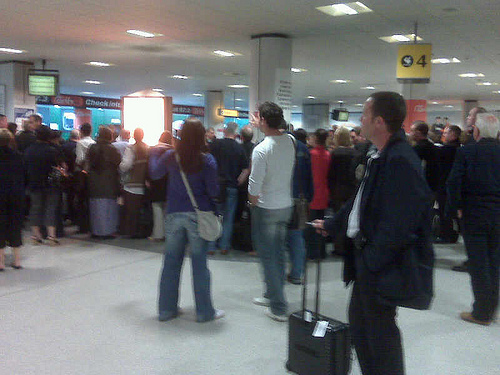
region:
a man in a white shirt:
[246, 101, 295, 322]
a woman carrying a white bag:
[143, 118, 228, 325]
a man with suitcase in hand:
[282, 88, 437, 374]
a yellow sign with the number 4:
[395, 36, 433, 82]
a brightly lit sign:
[120, 88, 173, 145]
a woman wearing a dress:
[80, 125, 127, 242]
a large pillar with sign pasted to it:
[249, 32, 293, 150]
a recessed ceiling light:
[313, 0, 374, 17]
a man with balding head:
[440, 111, 497, 326]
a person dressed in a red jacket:
[305, 126, 331, 261]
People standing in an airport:
[79, 128, 444, 265]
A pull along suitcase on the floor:
[287, 223, 350, 360]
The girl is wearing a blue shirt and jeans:
[153, 108, 230, 313]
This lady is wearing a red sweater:
[297, 118, 327, 223]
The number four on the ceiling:
[390, 36, 436, 77]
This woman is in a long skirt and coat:
[85, 138, 117, 238]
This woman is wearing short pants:
[0, 241, 26, 277]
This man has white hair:
[470, 108, 496, 144]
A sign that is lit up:
[217, 100, 239, 123]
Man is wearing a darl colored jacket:
[368, 132, 434, 303]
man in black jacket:
[357, 111, 438, 256]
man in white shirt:
[248, 108, 305, 255]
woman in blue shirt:
[162, 131, 238, 243]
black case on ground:
[290, 268, 345, 368]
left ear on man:
[369, 103, 389, 129]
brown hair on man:
[367, 99, 398, 129]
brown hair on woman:
[186, 130, 210, 174]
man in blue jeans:
[256, 194, 322, 311]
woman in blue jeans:
[164, 200, 242, 351]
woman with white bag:
[189, 157, 231, 259]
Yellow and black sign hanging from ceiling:
[392, 42, 436, 84]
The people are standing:
[0, 94, 492, 369]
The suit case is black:
[283, 217, 348, 367]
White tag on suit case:
[308, 319, 330, 339]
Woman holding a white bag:
[156, 119, 226, 324]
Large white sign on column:
[269, 62, 292, 120]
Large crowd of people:
[6, 102, 490, 374]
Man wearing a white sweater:
[248, 103, 308, 210]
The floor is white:
[3, 226, 495, 373]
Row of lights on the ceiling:
[38, 18, 491, 123]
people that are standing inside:
[58, 80, 475, 321]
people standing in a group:
[4, 51, 485, 374]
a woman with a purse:
[32, 80, 450, 291]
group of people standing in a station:
[55, 70, 476, 316]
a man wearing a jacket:
[314, 97, 440, 371]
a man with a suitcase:
[268, 137, 440, 372]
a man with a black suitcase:
[286, 141, 399, 366]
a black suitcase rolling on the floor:
[219, 130, 389, 358]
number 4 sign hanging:
[357, 1, 487, 159]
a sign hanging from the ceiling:
[339, 18, 447, 121]